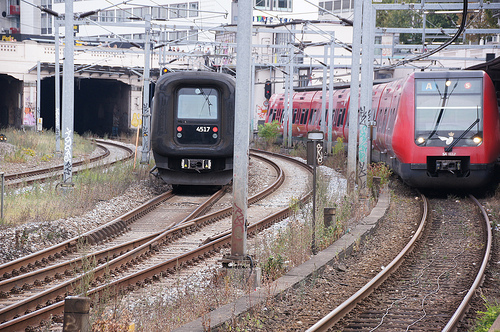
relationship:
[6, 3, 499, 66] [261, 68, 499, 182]
cables over train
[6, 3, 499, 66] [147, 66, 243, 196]
cables over train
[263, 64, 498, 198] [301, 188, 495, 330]
train on track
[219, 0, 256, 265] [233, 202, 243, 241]
metal pole with graffiti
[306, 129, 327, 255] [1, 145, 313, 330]
pole between tracks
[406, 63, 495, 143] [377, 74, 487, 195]
window on train